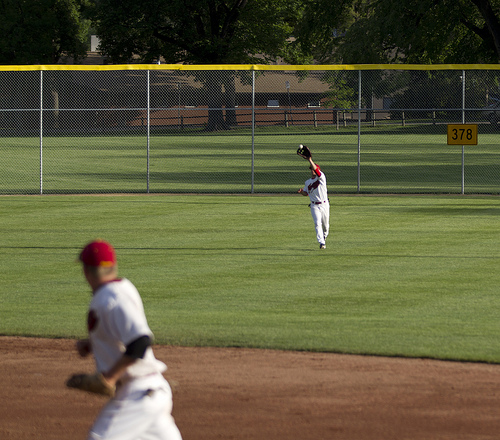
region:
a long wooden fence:
[28, 100, 494, 137]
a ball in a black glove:
[292, 136, 313, 159]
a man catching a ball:
[295, 140, 342, 255]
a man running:
[60, 245, 192, 435]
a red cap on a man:
[60, 242, 135, 268]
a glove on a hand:
[63, 366, 114, 399]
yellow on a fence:
[0, 58, 495, 75]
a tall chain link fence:
[4, 60, 497, 202]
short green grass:
[2, 122, 497, 360]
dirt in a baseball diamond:
[2, 330, 498, 439]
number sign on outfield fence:
[439, 116, 493, 185]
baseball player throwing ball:
[47, 233, 189, 439]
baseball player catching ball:
[265, 127, 366, 247]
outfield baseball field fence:
[5, 67, 475, 187]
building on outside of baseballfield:
[15, 76, 364, 133]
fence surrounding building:
[92, 114, 493, 134]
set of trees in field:
[328, 66, 493, 150]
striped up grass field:
[25, 199, 497, 351]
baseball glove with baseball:
[280, 133, 315, 163]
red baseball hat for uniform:
[59, 229, 120, 274]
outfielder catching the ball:
[280, 135, 351, 270]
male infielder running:
[63, 239, 190, 439]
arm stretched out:
[293, 141, 326, 176]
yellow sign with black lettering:
[442, 121, 485, 147]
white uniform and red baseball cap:
[71, 231, 182, 438]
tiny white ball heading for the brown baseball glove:
[294, 141, 312, 163]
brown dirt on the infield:
[3, 336, 498, 438]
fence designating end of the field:
[1, 62, 498, 192]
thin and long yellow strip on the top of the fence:
[0, 63, 499, 72]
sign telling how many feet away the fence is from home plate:
[445, 119, 485, 151]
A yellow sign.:
[436, 119, 493, 161]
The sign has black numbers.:
[439, 119, 481, 150]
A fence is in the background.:
[13, 65, 238, 195]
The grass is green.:
[223, 257, 453, 345]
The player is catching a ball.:
[283, 130, 351, 262]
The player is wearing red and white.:
[281, 127, 344, 259]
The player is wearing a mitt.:
[275, 136, 344, 262]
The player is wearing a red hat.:
[32, 220, 200, 437]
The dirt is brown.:
[207, 364, 357, 434]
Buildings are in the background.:
[110, 40, 337, 127]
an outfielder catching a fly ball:
[289, 137, 345, 257]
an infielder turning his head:
[53, 237, 186, 438]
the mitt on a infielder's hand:
[66, 371, 122, 399]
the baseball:
[296, 143, 305, 150]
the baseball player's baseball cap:
[76, 237, 119, 266]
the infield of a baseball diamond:
[172, 366, 487, 436]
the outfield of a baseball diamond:
[163, 249, 496, 329]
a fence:
[29, 80, 437, 125]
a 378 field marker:
[443, 120, 478, 147]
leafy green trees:
[11, 2, 495, 62]